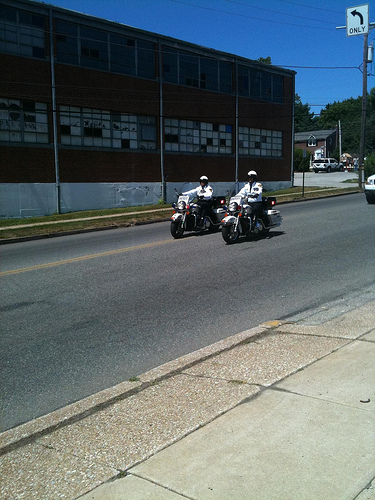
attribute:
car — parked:
[306, 147, 342, 180]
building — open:
[24, 9, 322, 262]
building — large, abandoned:
[8, 0, 321, 227]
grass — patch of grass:
[268, 184, 304, 191]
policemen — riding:
[179, 168, 263, 200]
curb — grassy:
[4, 178, 361, 257]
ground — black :
[264, 78, 305, 117]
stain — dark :
[0, 297, 47, 312]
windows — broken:
[78, 124, 107, 139]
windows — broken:
[258, 135, 271, 145]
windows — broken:
[164, 133, 178, 145]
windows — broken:
[13, 115, 36, 128]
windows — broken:
[202, 137, 213, 146]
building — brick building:
[8, 11, 291, 175]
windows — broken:
[59, 102, 157, 156]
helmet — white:
[246, 169, 258, 180]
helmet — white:
[200, 176, 209, 182]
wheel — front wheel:
[151, 210, 198, 234]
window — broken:
[60, 103, 141, 149]